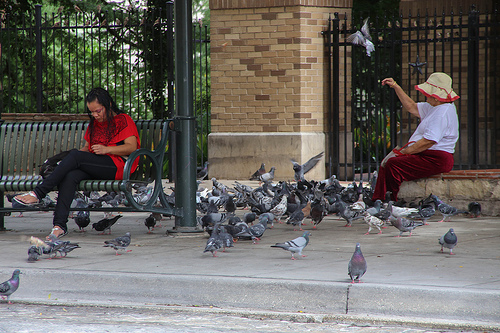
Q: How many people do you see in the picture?
A: Two.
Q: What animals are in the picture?
A: Pigeons.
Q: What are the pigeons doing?
A: Eating.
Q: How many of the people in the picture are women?
A: Both.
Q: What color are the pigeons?
A: Gray and white.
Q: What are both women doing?
A: Sitting.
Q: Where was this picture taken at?
A: In the city.